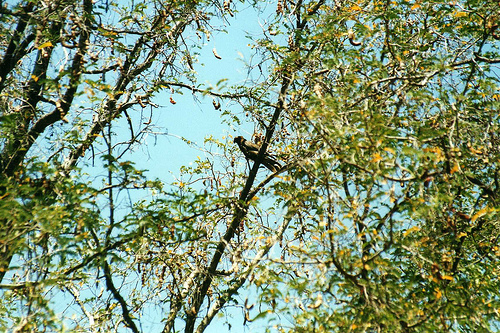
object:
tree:
[0, 0, 499, 333]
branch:
[0, 0, 499, 333]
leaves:
[0, 0, 499, 333]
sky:
[0, 0, 499, 333]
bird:
[233, 135, 283, 172]